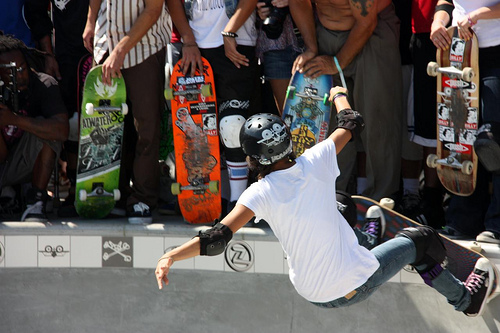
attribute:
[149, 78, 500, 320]
skateboarder — doing tricks, skateboarding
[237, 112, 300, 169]
helmet — black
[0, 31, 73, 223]
man — taking a picture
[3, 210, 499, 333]
ground — grey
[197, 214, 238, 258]
elbow pad — black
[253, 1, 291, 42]
camera — black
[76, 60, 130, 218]
skateboard — green, black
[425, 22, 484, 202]
skateboard — brown wood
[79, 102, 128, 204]
wheels — white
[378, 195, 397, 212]
wheel — white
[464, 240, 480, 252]
wheel — white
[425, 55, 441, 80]
skateboard wheel — white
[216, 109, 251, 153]
knee pad — white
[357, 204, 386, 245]
shoe — partly visible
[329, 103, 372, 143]
elbow pad — black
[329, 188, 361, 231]
knee pad — partly visible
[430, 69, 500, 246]
jeans — partly visible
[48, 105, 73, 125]
bicep — partly visible